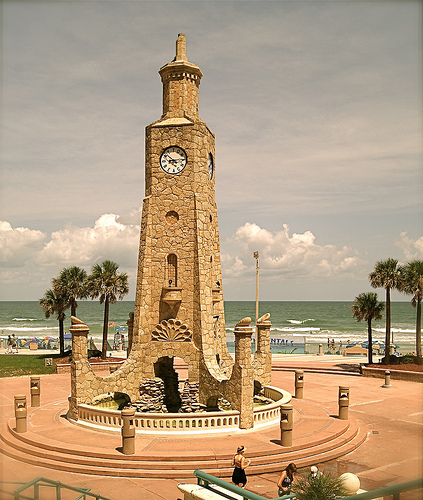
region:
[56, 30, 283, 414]
clock tower monument near a beach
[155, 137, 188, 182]
clock on the tower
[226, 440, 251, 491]
person near the tower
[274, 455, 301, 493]
person near the tower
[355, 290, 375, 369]
palm tree near the beach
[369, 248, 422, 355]
palm trees near the beach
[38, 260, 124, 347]
palm trees near the beach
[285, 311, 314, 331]
wave on the water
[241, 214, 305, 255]
cloud in the sky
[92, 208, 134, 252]
cloud in the sky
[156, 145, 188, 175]
A fully visible white and black clock.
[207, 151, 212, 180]
A barely visible side clock on a tower.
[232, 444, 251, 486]
A blonde woman with a black headband and black dress on.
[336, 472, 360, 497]
A large cream colored ball by a woman.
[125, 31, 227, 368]
A tall stone clock tower.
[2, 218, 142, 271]
A large strip of puffy white clouds to the left of a tower.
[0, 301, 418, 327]
A green body of water.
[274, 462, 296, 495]
A brown haired woman leaning over beside a blonde in a black dress.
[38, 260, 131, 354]
Three palm trees to the left of a tower.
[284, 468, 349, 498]
A long bladed green plant by a large round ball.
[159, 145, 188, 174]
a clock on the tower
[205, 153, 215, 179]
a clock on the side of the tower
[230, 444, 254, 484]
a woman is walking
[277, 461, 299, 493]
a woman is standing up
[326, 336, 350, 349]
people on the beach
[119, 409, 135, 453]
a concrete pillar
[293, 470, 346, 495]
a green plant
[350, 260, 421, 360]
three tall palm trees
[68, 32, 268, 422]
the tower is made of brown stone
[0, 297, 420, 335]
the ocean in the background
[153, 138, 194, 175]
large clock face on side of tower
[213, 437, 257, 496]
woman walking beside clock tower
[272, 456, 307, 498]
woman standing beside metal guard rail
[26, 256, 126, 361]
palm trees covered in leaves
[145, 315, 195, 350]
design on side of stone clock tower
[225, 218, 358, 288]
large white cloud in sky above water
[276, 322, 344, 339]
small waves covered in white sea foam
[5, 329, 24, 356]
couple walking down beach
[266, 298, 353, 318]
calm surface of clear blue water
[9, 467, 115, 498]
green metal guard railing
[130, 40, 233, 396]
a tall stone tower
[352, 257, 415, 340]
palm trees next to the water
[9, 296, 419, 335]
water behind the trees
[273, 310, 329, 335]
waves in the water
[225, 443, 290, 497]
people standing in front of the tower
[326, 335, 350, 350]
people standing on the beach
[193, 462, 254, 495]
a railing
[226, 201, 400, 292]
clouds in the sky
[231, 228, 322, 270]
a large white cloud